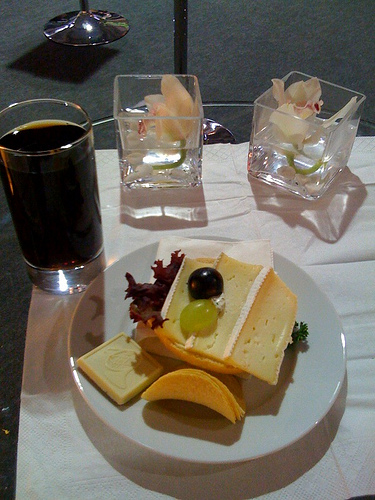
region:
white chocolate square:
[75, 330, 164, 407]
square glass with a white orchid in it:
[241, 68, 366, 206]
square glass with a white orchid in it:
[109, 72, 207, 196]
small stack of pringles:
[139, 360, 250, 425]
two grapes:
[174, 264, 225, 334]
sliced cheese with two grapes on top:
[142, 253, 304, 386]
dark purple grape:
[186, 264, 225, 300]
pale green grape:
[178, 296, 223, 332]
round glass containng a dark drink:
[0, 94, 109, 301]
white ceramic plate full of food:
[63, 229, 353, 471]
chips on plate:
[133, 362, 265, 425]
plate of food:
[90, 248, 339, 438]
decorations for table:
[116, 67, 365, 203]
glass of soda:
[5, 93, 112, 299]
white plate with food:
[120, 234, 350, 475]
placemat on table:
[16, 392, 82, 494]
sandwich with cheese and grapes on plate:
[147, 256, 301, 369]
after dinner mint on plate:
[80, 334, 165, 403]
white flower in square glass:
[266, 83, 359, 177]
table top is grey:
[203, 13, 368, 74]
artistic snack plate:
[66, 233, 345, 465]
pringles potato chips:
[143, 360, 249, 437]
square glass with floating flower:
[249, 68, 362, 205]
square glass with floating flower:
[108, 70, 205, 192]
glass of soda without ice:
[0, 98, 99, 298]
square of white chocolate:
[79, 335, 157, 406]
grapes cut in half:
[184, 264, 223, 351]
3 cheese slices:
[158, 252, 294, 382]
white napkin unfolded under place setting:
[17, 144, 373, 497]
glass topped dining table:
[0, 0, 374, 497]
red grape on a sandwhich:
[184, 261, 230, 299]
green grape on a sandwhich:
[177, 299, 230, 342]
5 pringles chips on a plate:
[141, 364, 254, 428]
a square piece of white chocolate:
[68, 327, 160, 406]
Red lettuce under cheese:
[109, 242, 172, 332]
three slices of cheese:
[150, 258, 286, 388]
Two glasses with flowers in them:
[92, 59, 361, 212]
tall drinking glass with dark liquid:
[2, 103, 112, 295]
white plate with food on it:
[68, 233, 350, 469]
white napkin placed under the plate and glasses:
[14, 134, 374, 490]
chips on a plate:
[137, 362, 256, 429]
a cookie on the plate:
[72, 334, 164, 406]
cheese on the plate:
[157, 249, 286, 392]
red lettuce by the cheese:
[121, 248, 185, 325]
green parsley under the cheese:
[290, 313, 313, 348]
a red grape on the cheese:
[182, 261, 228, 295]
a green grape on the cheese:
[177, 298, 223, 332]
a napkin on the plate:
[148, 226, 284, 286]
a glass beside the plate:
[0, 92, 109, 300]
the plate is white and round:
[63, 231, 362, 473]